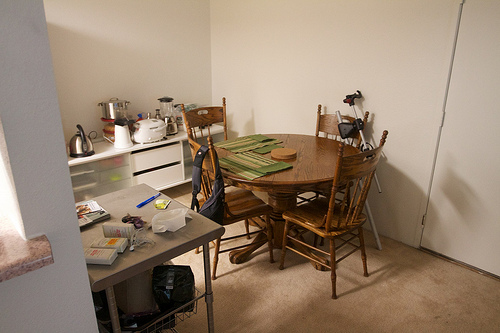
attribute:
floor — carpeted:
[201, 242, 428, 330]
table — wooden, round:
[203, 127, 366, 262]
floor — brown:
[218, 249, 494, 323]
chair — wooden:
[274, 124, 395, 303]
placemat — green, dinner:
[225, 132, 287, 186]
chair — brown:
[290, 132, 394, 294]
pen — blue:
[134, 190, 156, 210]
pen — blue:
[133, 187, 160, 212]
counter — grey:
[68, 173, 210, 296]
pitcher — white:
[111, 115, 132, 149]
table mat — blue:
[219, 143, 296, 183]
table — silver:
[148, 241, 183, 286]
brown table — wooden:
[192, 131, 353, 268]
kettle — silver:
[68, 123, 95, 158]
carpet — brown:
[140, 180, 497, 330]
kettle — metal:
[65, 118, 93, 159]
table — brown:
[199, 128, 390, 272]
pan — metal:
[93, 97, 136, 124]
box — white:
[86, 244, 120, 275]